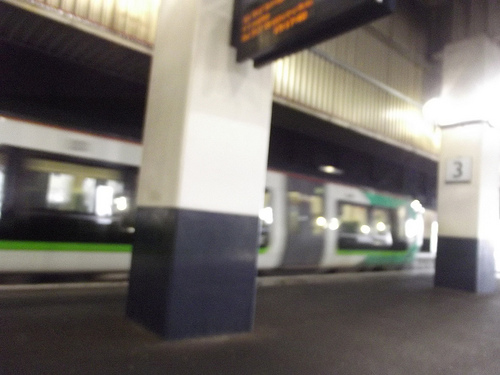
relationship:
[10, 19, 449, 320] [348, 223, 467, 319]
picture nt focused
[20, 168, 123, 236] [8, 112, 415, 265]
windows on train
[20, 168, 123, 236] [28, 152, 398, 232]
windows on subway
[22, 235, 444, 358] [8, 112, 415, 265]
plaform by train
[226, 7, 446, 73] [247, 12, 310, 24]
sign for arrivals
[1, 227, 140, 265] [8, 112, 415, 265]
stripe on train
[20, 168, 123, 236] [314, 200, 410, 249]
windows reflecting light